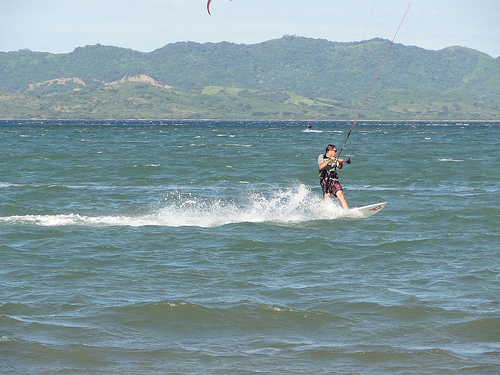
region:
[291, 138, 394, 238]
A person on skies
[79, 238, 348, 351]
Water is blue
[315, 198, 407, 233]
His board is white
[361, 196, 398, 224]
Logo on the board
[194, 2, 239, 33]
A object in the air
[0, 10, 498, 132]
Mountains in the background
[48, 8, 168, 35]
The sky is sunny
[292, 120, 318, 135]
Another person in the ocean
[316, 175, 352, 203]
He is wearing shorts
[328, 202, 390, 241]
white surf board on the water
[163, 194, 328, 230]
white water behind the surf board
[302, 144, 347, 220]
man on a surf board holding to a handle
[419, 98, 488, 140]
dark blue water by the shore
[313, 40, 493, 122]
mountains in the background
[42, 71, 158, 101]
dirt hills in the mountains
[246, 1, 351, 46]
a hazy day above the mountain top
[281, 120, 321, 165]
person in the water closer to shore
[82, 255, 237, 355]
shinny brown choppy water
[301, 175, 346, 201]
man with red and blue swim trunks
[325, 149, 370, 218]
man is on surfboard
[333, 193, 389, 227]
man's surfboard is white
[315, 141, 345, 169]
man has dark hair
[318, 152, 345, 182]
man has grey shirt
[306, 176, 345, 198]
man has red shorts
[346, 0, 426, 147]
man holds red cable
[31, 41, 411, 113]
green trees on hill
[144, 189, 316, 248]
man creates white wake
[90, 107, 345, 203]
small waves on water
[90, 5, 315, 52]
sky is light blue with thin clouds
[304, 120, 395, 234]
a person wind surfing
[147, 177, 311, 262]
a white spray left by the wind surfer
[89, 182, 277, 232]
wake left behind the wind surfer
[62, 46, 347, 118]
row of mountains in the distance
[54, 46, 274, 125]
hilly background by the water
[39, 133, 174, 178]
choppy blue water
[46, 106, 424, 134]
long empty shoreline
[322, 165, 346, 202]
shorts on a wind surfer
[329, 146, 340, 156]
sunglasses on a wind surfer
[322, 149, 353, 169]
handle in a wind surfer's hands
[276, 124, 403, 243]
a person riding a surfboard on the ocean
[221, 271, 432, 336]
calm blue water of the ocean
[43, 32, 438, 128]
rolling hills in the distance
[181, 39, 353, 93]
trees growing on the hills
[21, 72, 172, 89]
tan stone cliffs on the land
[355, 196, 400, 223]
a white surfboard in the water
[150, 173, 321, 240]
white water spray from the surfboard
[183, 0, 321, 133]
a person windsurfing on the ocean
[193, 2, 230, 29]
a red kite in the sky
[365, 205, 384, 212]
red logo on a white surfboard